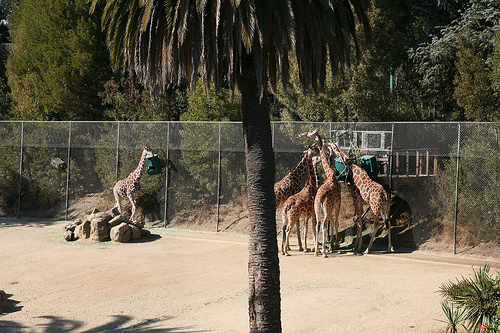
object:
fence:
[0, 118, 500, 264]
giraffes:
[297, 127, 343, 258]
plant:
[434, 263, 500, 333]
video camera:
[49, 156, 68, 170]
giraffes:
[324, 139, 396, 255]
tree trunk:
[240, 53, 286, 333]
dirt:
[0, 218, 500, 333]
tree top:
[3, 0, 112, 121]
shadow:
[0, 308, 212, 333]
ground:
[0, 217, 500, 333]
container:
[332, 156, 351, 180]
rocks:
[109, 222, 132, 243]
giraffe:
[273, 141, 306, 252]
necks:
[310, 136, 339, 182]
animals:
[112, 143, 160, 223]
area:
[1, 96, 500, 333]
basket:
[144, 153, 162, 175]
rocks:
[89, 217, 110, 242]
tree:
[68, 0, 461, 333]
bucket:
[358, 154, 379, 180]